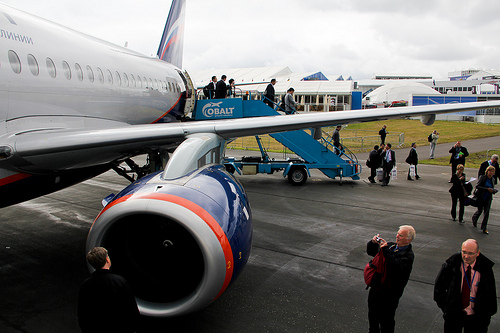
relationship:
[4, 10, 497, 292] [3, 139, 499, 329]
plane near runway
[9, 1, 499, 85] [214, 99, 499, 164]
sky above grass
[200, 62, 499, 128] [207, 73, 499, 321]
buildings behind people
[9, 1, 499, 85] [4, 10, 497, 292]
sky above plane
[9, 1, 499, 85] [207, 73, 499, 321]
sky above people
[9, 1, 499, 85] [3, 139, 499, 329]
sky above runway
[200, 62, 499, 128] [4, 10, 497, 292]
buildings near plane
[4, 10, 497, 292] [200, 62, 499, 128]
plane near buildings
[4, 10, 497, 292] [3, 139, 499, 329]
plane on runway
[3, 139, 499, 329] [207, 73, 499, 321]
runway under people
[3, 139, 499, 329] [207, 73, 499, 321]
runway below people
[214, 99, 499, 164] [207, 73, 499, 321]
grass near people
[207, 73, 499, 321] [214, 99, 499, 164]
people near grass